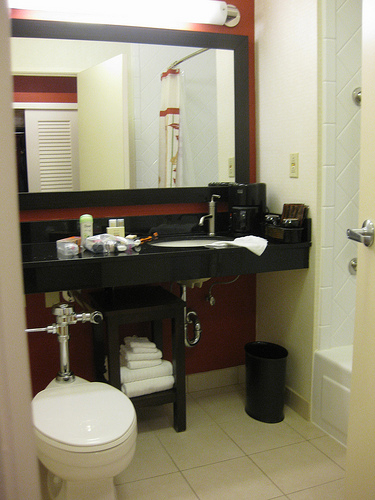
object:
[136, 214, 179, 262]
bike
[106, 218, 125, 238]
bottle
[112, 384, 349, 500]
tan floor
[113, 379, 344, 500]
tiles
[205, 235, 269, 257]
towel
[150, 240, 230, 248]
sink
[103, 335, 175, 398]
shelf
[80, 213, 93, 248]
dove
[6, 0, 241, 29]
light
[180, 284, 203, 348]
pipe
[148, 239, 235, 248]
sink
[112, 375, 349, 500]
floor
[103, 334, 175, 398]
towels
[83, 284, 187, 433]
shelf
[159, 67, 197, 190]
reflection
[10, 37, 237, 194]
bathroom mirror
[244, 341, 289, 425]
trash bin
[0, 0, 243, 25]
oblong light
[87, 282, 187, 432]
stool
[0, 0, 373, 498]
bathroom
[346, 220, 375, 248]
silver handle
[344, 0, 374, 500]
door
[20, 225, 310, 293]
counter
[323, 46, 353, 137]
white tile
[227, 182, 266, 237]
coffee maker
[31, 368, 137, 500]
toilet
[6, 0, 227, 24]
cover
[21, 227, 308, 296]
countertop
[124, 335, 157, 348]
towel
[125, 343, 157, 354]
towel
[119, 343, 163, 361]
towel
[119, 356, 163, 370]
towel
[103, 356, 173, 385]
towel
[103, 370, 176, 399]
towel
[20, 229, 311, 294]
counter